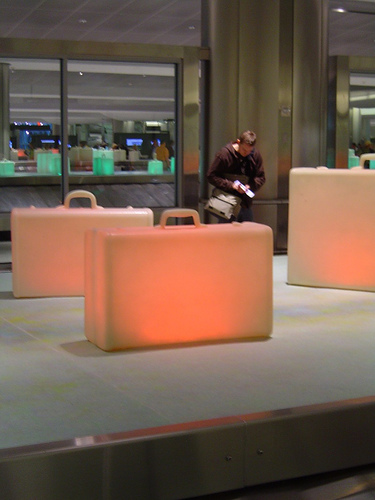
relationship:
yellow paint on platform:
[1, 303, 46, 330] [2, 251, 371, 478]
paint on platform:
[10, 365, 86, 405] [7, 236, 369, 459]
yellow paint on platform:
[7, 308, 47, 331] [2, 296, 89, 373]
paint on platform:
[274, 305, 362, 340] [2, 251, 371, 478]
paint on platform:
[274, 311, 362, 340] [11, 318, 368, 486]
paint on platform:
[274, 305, 362, 340] [135, 332, 365, 425]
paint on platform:
[274, 305, 362, 340] [7, 236, 369, 459]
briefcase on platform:
[14, 193, 158, 298] [2, 251, 371, 478]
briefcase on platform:
[83, 204, 274, 345] [2, 251, 371, 478]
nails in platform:
[222, 441, 267, 466] [2, 251, 371, 478]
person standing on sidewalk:
[207, 130, 267, 222] [0, 238, 375, 451]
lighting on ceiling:
[64, 12, 201, 37] [26, 50, 350, 101]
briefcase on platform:
[91, 198, 287, 366] [76, 323, 284, 415]